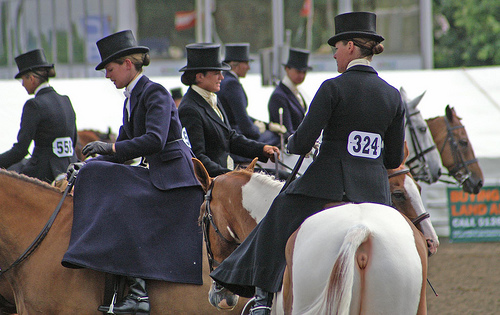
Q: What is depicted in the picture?
A: An old fashioned horse show.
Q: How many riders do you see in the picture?
A: 6.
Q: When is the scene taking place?
A: During the afternoon.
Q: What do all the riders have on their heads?
A: Top hats.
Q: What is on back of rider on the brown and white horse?
A: 324.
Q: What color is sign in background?
A: Green with orange and white letters.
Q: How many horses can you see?
A: 6.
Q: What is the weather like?
A: Sunny and clear.